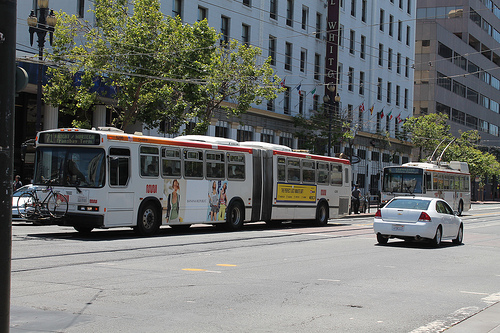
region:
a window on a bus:
[142, 145, 162, 175]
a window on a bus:
[108, 145, 131, 181]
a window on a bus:
[161, 145, 182, 177]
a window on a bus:
[180, 147, 206, 182]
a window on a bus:
[203, 147, 229, 179]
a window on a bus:
[225, 152, 246, 184]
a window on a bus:
[274, 152, 284, 177]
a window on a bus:
[287, 160, 303, 179]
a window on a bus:
[304, 161, 316, 187]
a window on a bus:
[319, 162, 329, 185]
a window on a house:
[194, 4, 206, 38]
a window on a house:
[438, 71, 451, 88]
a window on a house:
[383, 45, 395, 71]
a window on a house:
[353, 72, 368, 88]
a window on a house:
[278, 84, 290, 116]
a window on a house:
[266, 29, 280, 61]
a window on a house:
[234, 18, 256, 55]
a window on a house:
[281, 85, 310, 112]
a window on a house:
[436, 41, 454, 65]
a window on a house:
[453, 50, 466, 68]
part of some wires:
[450, 49, 485, 78]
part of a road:
[308, 247, 352, 274]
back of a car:
[381, 201, 444, 268]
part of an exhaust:
[408, 230, 429, 245]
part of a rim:
[137, 207, 160, 233]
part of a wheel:
[141, 206, 158, 228]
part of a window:
[183, 152, 226, 178]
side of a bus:
[150, 149, 203, 199]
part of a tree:
[169, 39, 236, 104]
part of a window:
[58, 146, 88, 171]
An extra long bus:
[13, 122, 355, 250]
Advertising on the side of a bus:
[146, 175, 330, 222]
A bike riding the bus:
[16, 172, 78, 225]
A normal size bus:
[377, 155, 494, 217]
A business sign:
[323, 0, 345, 141]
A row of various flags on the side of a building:
[264, 72, 456, 140]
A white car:
[370, 194, 475, 253]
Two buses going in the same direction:
[16, 117, 498, 238]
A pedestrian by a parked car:
[8, 168, 35, 220]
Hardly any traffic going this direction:
[87, 189, 496, 324]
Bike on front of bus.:
[6, 149, 105, 284]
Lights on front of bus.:
[66, 197, 139, 245]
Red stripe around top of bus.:
[112, 120, 353, 191]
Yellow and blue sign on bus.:
[283, 172, 363, 276]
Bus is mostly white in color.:
[116, 168, 303, 238]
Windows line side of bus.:
[145, 149, 297, 189]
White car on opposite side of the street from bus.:
[386, 180, 458, 305]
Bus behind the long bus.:
[376, 127, 483, 232]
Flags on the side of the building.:
[243, 75, 450, 130]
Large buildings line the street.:
[248, 82, 462, 137]